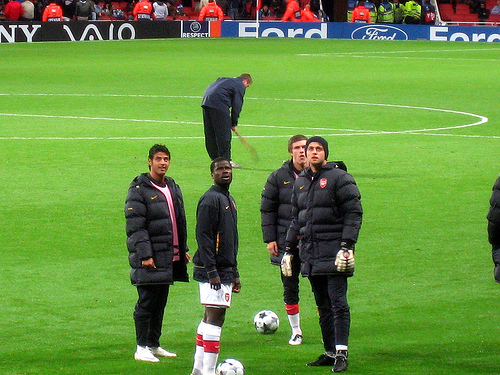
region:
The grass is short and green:
[7, 154, 117, 367]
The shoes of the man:
[123, 335, 179, 362]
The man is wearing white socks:
[191, 316, 233, 373]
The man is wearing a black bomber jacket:
[127, 168, 197, 293]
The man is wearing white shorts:
[193, 273, 238, 312]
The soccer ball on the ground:
[248, 300, 282, 339]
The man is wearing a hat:
[298, 127, 333, 164]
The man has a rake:
[228, 108, 265, 175]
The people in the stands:
[8, 2, 478, 39]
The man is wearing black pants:
[294, 267, 364, 356]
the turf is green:
[32, 57, 371, 282]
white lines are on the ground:
[74, 65, 486, 370]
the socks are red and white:
[188, 304, 220, 359]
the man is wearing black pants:
[287, 277, 395, 360]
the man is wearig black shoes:
[300, 344, 362, 371]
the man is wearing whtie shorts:
[199, 283, 271, 318]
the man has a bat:
[212, 108, 314, 188]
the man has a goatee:
[210, 163, 270, 205]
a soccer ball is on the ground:
[237, 283, 379, 360]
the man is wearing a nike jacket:
[298, 174, 330, 209]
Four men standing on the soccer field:
[123, 130, 364, 371]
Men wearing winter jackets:
[258, 131, 363, 371]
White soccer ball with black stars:
[253, 306, 280, 339]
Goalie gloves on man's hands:
[279, 246, 354, 277]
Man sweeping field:
[199, 67, 259, 172]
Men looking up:
[122, 135, 237, 374]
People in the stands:
[0, 0, 492, 25]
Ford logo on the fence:
[348, 22, 408, 42]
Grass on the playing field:
[0, 41, 497, 373]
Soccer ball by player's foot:
[212, 354, 248, 373]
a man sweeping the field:
[199, 73, 261, 163]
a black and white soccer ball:
[252, 307, 280, 337]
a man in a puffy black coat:
[281, 136, 372, 373]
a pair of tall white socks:
[186, 323, 223, 374]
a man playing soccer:
[183, 158, 241, 373]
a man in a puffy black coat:
[119, 142, 194, 365]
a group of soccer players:
[116, 132, 371, 374]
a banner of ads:
[1, 18, 496, 43]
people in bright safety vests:
[348, 0, 426, 25]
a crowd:
[1, 0, 318, 20]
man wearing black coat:
[121, 134, 193, 293]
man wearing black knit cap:
[303, 133, 329, 166]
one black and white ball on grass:
[251, 303, 282, 338]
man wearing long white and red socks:
[187, 155, 243, 374]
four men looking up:
[93, 129, 411, 374]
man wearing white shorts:
[192, 150, 241, 315]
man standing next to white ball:
[189, 155, 248, 373]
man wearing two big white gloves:
[278, 135, 359, 284]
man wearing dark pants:
[282, 131, 364, 368]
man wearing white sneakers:
[117, 141, 191, 361]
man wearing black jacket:
[125, 143, 193, 311]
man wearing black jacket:
[264, 170, 300, 242]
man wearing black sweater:
[205, 65, 240, 106]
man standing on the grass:
[205, 135, 255, 325]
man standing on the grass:
[300, 135, 350, 325]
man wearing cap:
[308, 134, 333, 180]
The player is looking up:
[187, 158, 242, 373]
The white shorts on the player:
[197, 278, 232, 310]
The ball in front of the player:
[217, 358, 246, 374]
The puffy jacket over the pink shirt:
[127, 169, 193, 286]